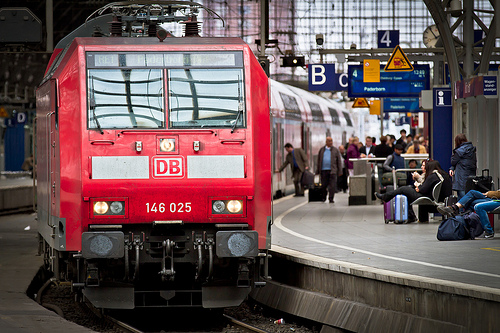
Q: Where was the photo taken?
A: Train station.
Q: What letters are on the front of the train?
A: DB.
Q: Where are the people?
A: On the platform.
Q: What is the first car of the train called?
A: The engine.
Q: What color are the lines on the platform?
A: White.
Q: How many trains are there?
A: 1.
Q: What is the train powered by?
A: Electric.